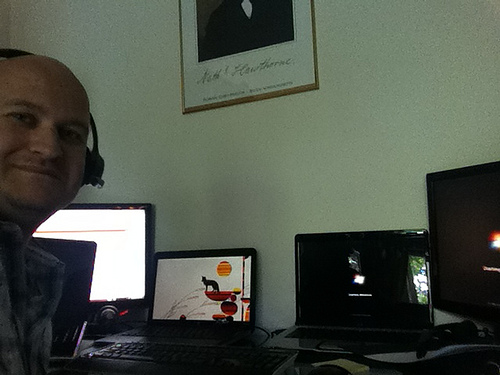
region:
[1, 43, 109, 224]
A man wearing headphones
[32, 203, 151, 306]
Computer screen is turned on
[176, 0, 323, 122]
A framed photo on the wall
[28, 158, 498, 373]
Five computers on a desk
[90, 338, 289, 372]
Black keys on a keyboard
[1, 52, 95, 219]
The man is bald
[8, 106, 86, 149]
A pair of eyes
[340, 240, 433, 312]
Reflections on the screen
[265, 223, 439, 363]
A laptop is starting up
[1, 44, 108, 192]
The headphones are black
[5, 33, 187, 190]
the head of a man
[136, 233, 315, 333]
the screen of a laptop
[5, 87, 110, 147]
the eyes of a man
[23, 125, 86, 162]
the nose of a man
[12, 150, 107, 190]
the mouth of a man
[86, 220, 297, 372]
a laptop on a desk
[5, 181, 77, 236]
the chin of a man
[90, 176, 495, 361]
two laptops on a desk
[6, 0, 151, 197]
a man wearing head phones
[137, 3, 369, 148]
a picture on a wall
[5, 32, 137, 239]
man is wearing headphones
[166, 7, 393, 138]
a picture on the wall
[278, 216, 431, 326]
Small black computer screen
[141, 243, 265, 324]
Small black computer screen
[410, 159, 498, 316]
Small black computer screen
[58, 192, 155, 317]
Small black computer screen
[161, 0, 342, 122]
Large picture on the wall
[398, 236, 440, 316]
Reflection in the screen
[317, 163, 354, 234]
Small part of white wall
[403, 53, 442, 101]
Small part of white wall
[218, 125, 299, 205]
Small part of white wall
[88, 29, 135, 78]
Small part of white wall